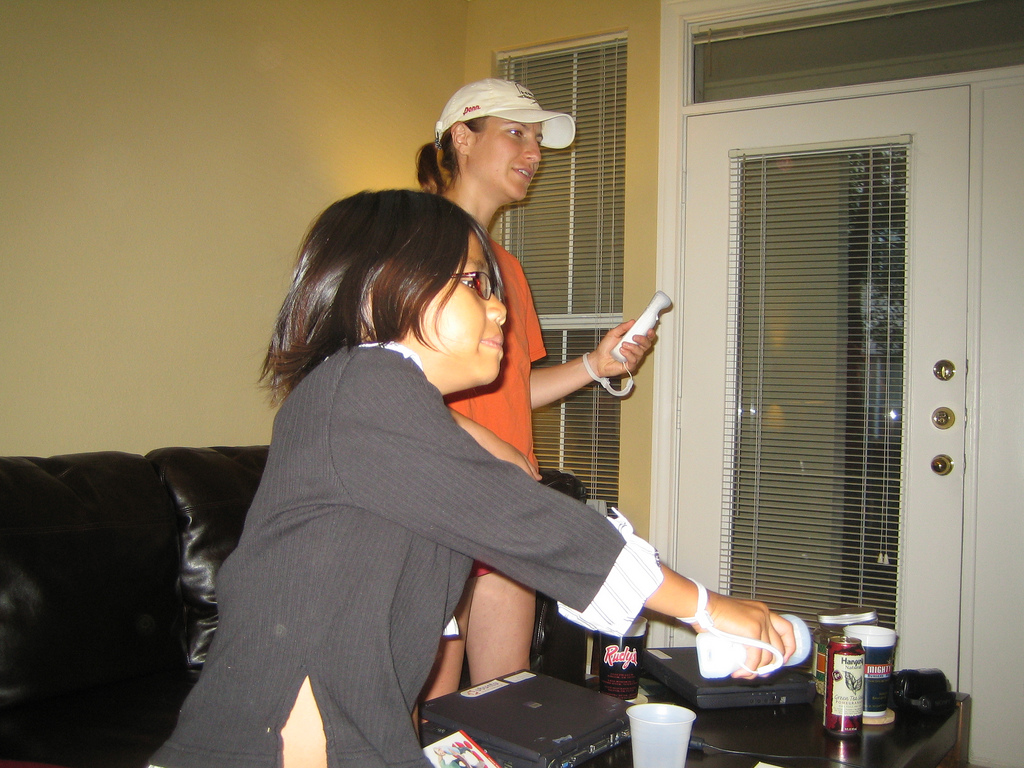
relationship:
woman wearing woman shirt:
[408, 72, 659, 702] [440, 224, 549, 482]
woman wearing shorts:
[408, 72, 659, 702] [475, 558, 497, 578]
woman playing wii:
[138, 186, 797, 764] [564, 271, 843, 720]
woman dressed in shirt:
[408, 81, 650, 702] [443, 230, 549, 479]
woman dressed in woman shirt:
[125, 172, 798, 764] [143, 334, 664, 766]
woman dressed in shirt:
[125, 172, 798, 764] [347, 336, 665, 641]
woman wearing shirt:
[408, 81, 650, 702] [449, 219, 538, 474]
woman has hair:
[125, 172, 798, 764] [246, 177, 510, 391]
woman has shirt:
[125, 172, 798, 764] [113, 338, 667, 766]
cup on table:
[622, 696, 696, 764] [435, 609, 965, 765]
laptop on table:
[632, 630, 809, 710] [495, 630, 979, 764]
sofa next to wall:
[0, 442, 589, 763] [7, 14, 682, 613]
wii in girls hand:
[691, 606, 817, 685] [695, 585, 794, 677]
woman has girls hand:
[125, 172, 798, 764] [695, 585, 794, 677]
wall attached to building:
[2, 0, 478, 453] [7, 21, 1016, 750]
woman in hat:
[408, 72, 659, 702] [429, 72, 590, 173]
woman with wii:
[408, 72, 659, 702] [691, 606, 817, 685]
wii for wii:
[691, 606, 817, 685] [705, 594, 827, 668]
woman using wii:
[408, 72, 659, 702] [691, 606, 817, 685]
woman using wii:
[408, 72, 659, 702] [610, 288, 675, 367]